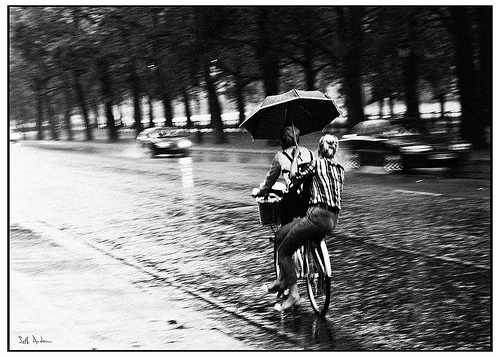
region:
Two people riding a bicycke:
[226, 73, 363, 337]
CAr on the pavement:
[344, 89, 456, 208]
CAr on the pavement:
[130, 116, 222, 181]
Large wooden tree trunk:
[198, 86, 240, 158]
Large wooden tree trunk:
[175, 90, 202, 130]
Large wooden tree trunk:
[149, 98, 179, 126]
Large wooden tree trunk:
[144, 98, 160, 126]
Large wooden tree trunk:
[125, 96, 142, 132]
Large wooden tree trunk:
[95, 101, 120, 136]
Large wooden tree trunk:
[75, 98, 100, 150]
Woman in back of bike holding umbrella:
[240, 88, 345, 317]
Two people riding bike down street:
[237, 75, 347, 317]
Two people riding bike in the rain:
[238, 73, 346, 318]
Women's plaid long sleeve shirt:
[299, 154, 345, 212]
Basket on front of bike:
[258, 191, 283, 223]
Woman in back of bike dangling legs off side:
[268, 133, 347, 310]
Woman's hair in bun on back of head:
[316, 133, 338, 158]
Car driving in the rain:
[135, 126, 196, 157]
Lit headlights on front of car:
[155, 138, 192, 148]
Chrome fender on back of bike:
[318, 237, 333, 277]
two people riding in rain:
[269, 128, 359, 318]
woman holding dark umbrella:
[250, 74, 328, 123]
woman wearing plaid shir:
[305, 170, 380, 215]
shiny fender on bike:
[310, 238, 345, 284]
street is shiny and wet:
[38, 142, 74, 223]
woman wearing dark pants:
[291, 217, 341, 252]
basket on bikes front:
[254, 198, 281, 230]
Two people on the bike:
[213, 82, 370, 334]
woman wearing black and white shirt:
[294, 155, 358, 210]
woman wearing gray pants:
[251, 212, 351, 282]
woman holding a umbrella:
[228, 81, 346, 168]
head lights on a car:
[151, 135, 193, 149]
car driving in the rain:
[329, 100, 481, 175]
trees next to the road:
[89, 63, 257, 124]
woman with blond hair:
[316, 128, 344, 164]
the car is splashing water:
[132, 125, 194, 158]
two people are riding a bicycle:
[244, 85, 356, 307]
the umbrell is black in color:
[243, 89, 340, 145]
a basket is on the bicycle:
[259, 194, 283, 225]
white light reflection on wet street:
[18, 151, 130, 226]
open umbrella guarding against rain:
[235, 75, 340, 130]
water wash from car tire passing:
[107, 134, 148, 156]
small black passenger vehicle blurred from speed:
[347, 112, 476, 179]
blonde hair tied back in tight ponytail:
[311, 127, 339, 157]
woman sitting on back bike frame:
[276, 136, 352, 315]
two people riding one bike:
[250, 116, 352, 313]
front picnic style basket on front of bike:
[255, 192, 290, 223]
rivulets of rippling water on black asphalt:
[140, 165, 240, 298]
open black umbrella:
[237, 88, 339, 161]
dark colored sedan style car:
[136, 125, 192, 157]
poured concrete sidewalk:
[10, 218, 252, 349]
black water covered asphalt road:
[9, 143, 492, 351]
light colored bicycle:
[253, 178, 332, 316]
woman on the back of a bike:
[272, 133, 345, 312]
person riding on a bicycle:
[249, 121, 334, 297]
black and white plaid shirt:
[288, 155, 346, 210]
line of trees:
[6, 8, 491, 145]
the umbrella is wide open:
[240, 90, 340, 142]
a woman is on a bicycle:
[276, 134, 350, 311]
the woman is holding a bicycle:
[288, 140, 300, 181]